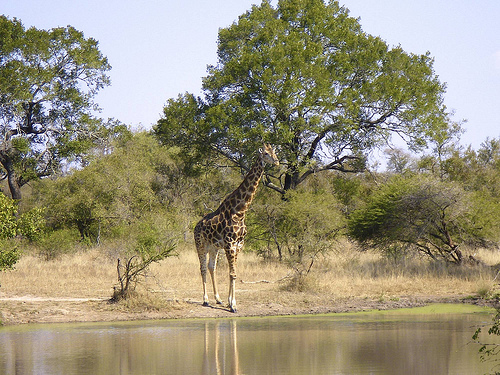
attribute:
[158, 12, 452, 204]
tree — Tall 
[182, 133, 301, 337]
giraffe — spotted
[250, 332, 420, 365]
water — brown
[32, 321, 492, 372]
water — still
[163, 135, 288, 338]
giraffe — brown , yellow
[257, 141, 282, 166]
giraffe — tall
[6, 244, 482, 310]
grass — brown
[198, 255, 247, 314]
legs — giraffe's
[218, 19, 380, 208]
tree — tall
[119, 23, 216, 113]
sky — clear, blue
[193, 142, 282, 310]
giraffe — tall, standing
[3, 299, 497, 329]
moss — green